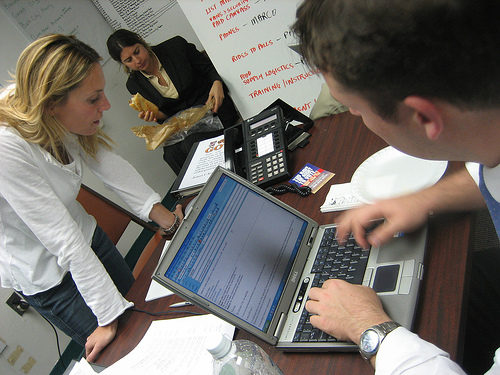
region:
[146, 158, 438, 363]
open silver laptop on table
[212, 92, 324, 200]
black phone on desk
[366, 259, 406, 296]
black trackpad on laptop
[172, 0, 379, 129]
white board with writing on it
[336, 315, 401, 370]
metal watch on wrist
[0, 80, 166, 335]
long sleeve white shirt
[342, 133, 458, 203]
empty paper plate on wooden desk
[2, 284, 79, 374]
black wall outlet with cord in it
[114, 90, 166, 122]
hoagie sandwich in hand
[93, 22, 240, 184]
woman holding a half of a hoagie sandwich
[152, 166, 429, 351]
Laptop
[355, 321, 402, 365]
Silver watch worn by the person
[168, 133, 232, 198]
Folder with several files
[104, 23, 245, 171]
Employee eating a burrito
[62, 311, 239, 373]
Set of papers on the table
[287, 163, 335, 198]
Small blue planner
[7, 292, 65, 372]
Plug port behind the lady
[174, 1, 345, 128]
Dry erase board with writing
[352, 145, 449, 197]
Paper plate next to the laptop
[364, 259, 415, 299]
Touch pad on the computer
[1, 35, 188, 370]
a woman is leaning over a desk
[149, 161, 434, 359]
laptop is open and switched on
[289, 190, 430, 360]
hands typing on a laptop keyboard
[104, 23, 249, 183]
a woman is eating a sandwich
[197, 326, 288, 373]
bottle of water on a desk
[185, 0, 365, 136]
whiteboard with red and black writing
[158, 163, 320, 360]
an email is being composed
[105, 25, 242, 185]
woman is wearing a black work suit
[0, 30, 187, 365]
blonde woman wearing a white shirt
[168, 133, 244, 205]
folder of papers on the corner of a desk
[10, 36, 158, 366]
woman wearing white shirt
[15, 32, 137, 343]
woman wearing blue jeans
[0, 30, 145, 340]
woman lean on a desk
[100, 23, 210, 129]
woman wearing black jacket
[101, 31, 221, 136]
woman eating a sandwich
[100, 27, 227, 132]
woman wearing black pants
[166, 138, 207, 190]
binder on a desk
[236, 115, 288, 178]
phone on a desk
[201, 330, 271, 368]
water on a desk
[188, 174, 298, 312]
laptop on a desk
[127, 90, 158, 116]
A sandwich being eaten.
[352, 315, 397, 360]
A man's silver wrist watch.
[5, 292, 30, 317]
An electric outlet for a plug.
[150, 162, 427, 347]
An open laptop computer.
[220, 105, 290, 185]
A black desk phone.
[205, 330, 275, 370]
A partially visible clear plastic bottle.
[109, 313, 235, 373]
A sheet of white paper.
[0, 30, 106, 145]
A female's head with blond hair.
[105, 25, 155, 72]
A female's head with dark hair.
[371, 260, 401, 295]
The laptop computer's track pad.